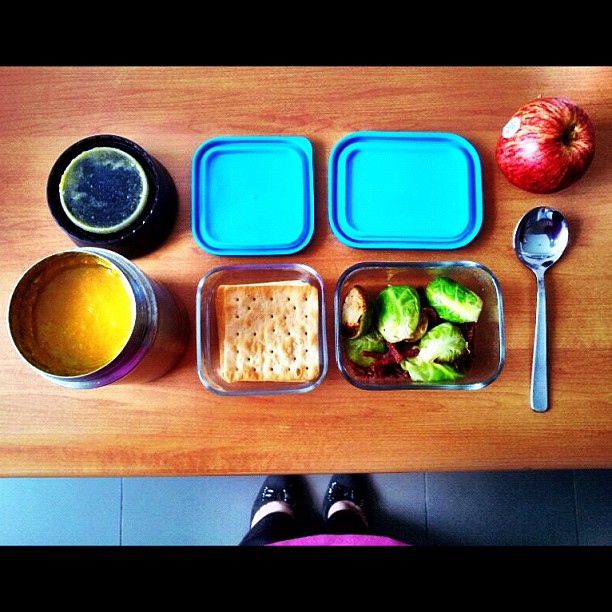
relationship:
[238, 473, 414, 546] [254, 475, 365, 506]
person wearing shoes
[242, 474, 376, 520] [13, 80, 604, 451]
feet are near table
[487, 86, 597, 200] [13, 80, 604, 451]
apple on table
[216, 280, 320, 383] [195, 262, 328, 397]
cracker are in container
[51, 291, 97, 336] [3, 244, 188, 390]
cheese in container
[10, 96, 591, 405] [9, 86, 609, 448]
food on top of board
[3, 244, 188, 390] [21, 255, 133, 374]
container containing soup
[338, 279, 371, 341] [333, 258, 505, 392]
brussels sprout lying inside bowl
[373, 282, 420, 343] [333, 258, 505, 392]
brussels sprout lying inside bowl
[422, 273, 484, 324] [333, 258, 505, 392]
brussels sprout lying inside bowl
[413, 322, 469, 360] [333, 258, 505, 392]
brussels sprout lying inside bowl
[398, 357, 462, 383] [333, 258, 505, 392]
brussels sprout lying inside bowl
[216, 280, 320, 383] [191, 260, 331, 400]
cracker lying inside container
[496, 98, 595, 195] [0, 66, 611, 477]
apple lying on top of table top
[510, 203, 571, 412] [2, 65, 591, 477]
spoon lying on top of table top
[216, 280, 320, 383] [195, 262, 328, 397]
cracker lying inside container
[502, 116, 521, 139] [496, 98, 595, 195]
sticker placed on apple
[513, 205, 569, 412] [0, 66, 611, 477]
spoon on table top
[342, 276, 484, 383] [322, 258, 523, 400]
sprouts in bowl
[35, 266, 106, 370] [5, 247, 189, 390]
cheese in container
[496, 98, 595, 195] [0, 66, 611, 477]
apple on table top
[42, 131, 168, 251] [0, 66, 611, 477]
cover on table top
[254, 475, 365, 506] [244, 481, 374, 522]
shoes on feet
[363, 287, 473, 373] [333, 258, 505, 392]
sprouts in bowl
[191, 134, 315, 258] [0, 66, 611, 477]
lids on table top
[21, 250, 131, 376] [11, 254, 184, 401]
soup in canister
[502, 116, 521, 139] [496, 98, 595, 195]
sticker on apple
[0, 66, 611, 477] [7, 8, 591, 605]
table top in room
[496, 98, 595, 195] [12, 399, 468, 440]
apple on table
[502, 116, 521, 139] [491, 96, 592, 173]
sticker on apple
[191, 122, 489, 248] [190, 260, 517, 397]
lids to containers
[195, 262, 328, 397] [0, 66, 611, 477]
container on table top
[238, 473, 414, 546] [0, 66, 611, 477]
person standing table top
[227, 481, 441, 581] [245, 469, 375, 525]
person wearing shoes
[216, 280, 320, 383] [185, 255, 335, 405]
cracker in container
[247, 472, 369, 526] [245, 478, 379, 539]
shoes on feet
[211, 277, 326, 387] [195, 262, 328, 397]
cracker in container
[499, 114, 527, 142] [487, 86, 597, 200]
sticker on apple